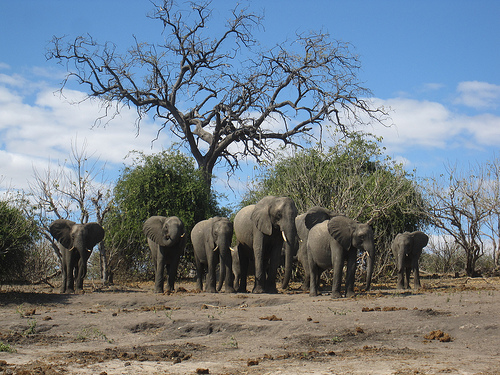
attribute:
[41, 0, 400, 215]
tree — large, leafless, bare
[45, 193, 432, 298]
elephants — Herd , gray, grey, standing, walking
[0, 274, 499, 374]
ground — large, dusty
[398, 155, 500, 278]
tree — small, dead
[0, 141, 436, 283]
trees — green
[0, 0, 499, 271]
sky — blue, big, clear, cloudy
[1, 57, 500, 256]
clouds — white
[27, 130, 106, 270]
tree — dead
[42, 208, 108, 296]
elephant — standing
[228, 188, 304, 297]
elephant — tall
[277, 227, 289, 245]
tusk — white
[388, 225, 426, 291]
elephant — small